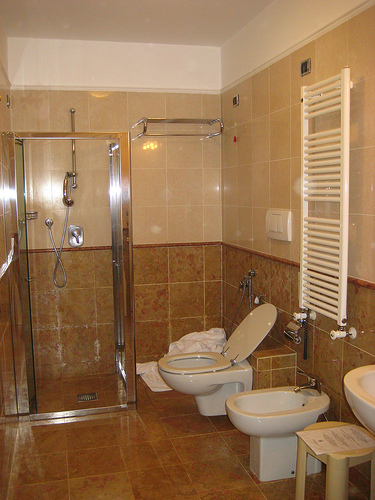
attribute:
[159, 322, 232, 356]
towels — white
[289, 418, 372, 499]
stool — plastic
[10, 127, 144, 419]
shower — silver framed, clear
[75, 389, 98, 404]
drain — silver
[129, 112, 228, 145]
bar — silver, metal, chrome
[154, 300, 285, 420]
toilet — white, beige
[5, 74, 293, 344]
wall — tiled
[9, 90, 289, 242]
tile — light brown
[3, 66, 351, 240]
bathroom — beige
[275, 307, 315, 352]
dispenser — chrome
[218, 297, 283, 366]
lid — up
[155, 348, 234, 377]
sit — plastic, down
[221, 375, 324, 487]
sink — white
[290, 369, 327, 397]
faucet — silver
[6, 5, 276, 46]
ceiling — white